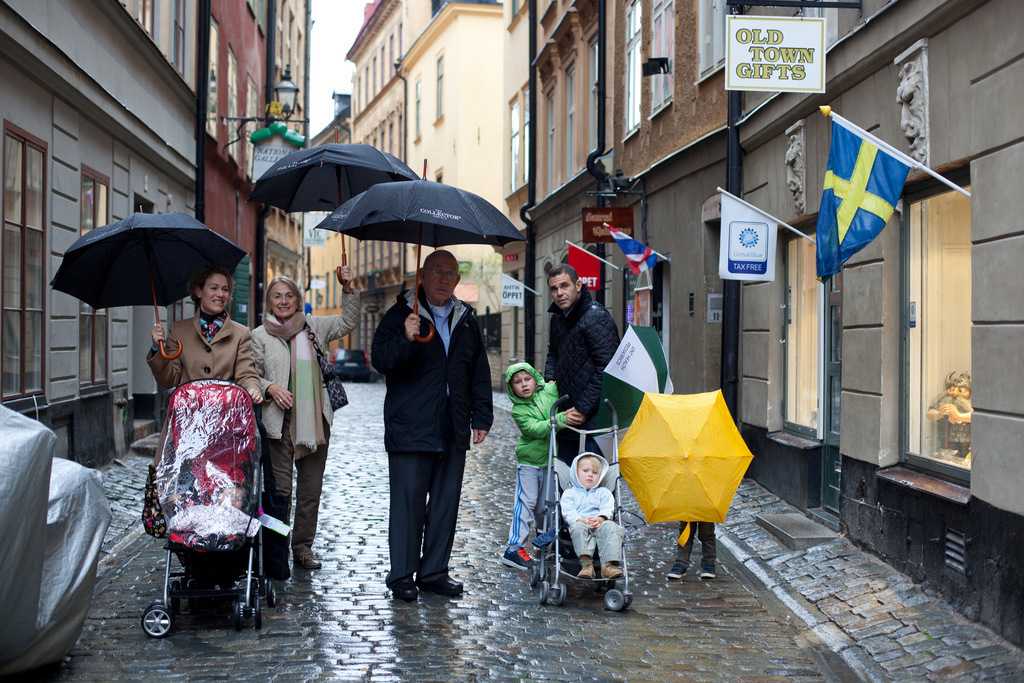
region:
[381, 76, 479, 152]
a view of building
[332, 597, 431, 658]
a view of road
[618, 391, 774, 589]
a beautiful yellow umbrella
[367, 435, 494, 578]
legs of the person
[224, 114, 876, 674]
a group of people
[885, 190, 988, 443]
a view of door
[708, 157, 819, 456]
a view of flag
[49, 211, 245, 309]
an opened black umbrella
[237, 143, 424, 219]
an opened black umbrella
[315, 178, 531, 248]
an opened black umbrella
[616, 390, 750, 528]
an opened yellow umbrella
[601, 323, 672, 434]
an opened green and white umbrella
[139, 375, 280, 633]
a baby in a baby stroller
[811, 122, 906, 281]
a waving Denmark flag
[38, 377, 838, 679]
a wet cobblestone street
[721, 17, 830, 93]
a business promotional sign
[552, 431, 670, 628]
the baby is in stroller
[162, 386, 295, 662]
plastic over the stroller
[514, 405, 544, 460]
the jacket is green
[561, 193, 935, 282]
the flag is flying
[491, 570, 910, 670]
the walkway is wet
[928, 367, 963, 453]
figure in the window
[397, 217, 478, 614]
the man is standing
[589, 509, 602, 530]
An Asian woman is holding a purse.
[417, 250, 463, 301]
Head of a man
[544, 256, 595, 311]
Head of a man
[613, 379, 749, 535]
Umbrella is visible and yellow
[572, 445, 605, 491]
Head of a boy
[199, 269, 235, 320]
Head of a woman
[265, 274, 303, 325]
Head of a woman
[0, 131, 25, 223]
building has a window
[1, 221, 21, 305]
building has a window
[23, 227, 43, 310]
building has a window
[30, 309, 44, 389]
building has a window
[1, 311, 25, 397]
building has a window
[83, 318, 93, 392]
building has a window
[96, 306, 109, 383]
building has a window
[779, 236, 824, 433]
building has a window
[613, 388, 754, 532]
yellow umbrella shielding child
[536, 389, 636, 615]
small child riding in umbrella stroller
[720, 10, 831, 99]
yellow and white business sign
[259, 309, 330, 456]
colorful scarf tied around woman's neck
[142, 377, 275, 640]
stroller covered with plastic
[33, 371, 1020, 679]
shiny wet road composed of stone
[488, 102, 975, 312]
array of flags posted beside windows of businesses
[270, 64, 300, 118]
street lamp affixed to building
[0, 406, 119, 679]
covered cycle on street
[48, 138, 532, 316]
three black umbrellas with red handles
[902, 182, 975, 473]
glass window on the building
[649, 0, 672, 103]
glass window on the building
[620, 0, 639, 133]
glass window on the building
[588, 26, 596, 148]
glass window on the building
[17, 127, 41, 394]
glass window on the building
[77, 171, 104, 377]
glass window on the building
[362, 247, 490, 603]
A person is standing up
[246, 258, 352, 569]
A person is standing up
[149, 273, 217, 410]
A person is standing up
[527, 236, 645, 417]
A person is standing up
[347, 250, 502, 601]
A person walking on a street.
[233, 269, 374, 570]
A person walking on a street.